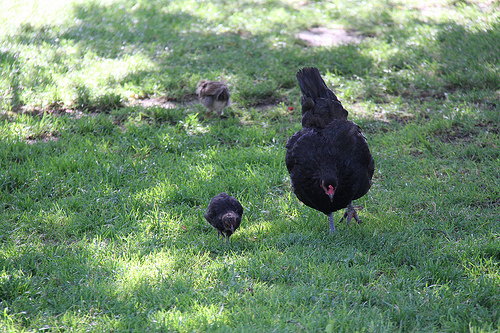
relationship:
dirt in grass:
[150, 87, 193, 121] [113, 149, 157, 200]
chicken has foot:
[200, 190, 245, 240] [217, 235, 234, 244]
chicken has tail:
[200, 190, 245, 240] [209, 196, 229, 204]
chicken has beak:
[301, 84, 369, 239] [323, 195, 336, 203]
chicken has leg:
[200, 190, 245, 240] [228, 232, 238, 255]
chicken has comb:
[301, 84, 369, 239] [328, 183, 335, 198]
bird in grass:
[199, 79, 229, 114] [113, 149, 157, 200]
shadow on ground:
[47, 95, 94, 132] [60, 177, 187, 301]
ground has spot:
[60, 177, 187, 301] [81, 204, 126, 244]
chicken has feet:
[200, 190, 245, 240] [215, 227, 236, 246]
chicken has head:
[200, 190, 245, 240] [222, 210, 239, 229]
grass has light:
[113, 149, 157, 200] [68, 60, 108, 88]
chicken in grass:
[200, 190, 245, 240] [113, 149, 157, 200]